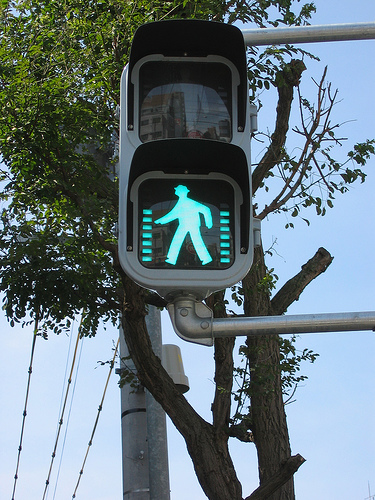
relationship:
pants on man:
[164, 224, 215, 267] [154, 184, 214, 265]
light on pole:
[113, 21, 255, 287] [171, 295, 374, 343]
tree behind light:
[0, 1, 375, 499] [113, 21, 255, 287]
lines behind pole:
[7, 297, 127, 498] [171, 295, 374, 343]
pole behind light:
[116, 288, 171, 498] [113, 21, 255, 287]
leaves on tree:
[0, 1, 372, 426] [0, 1, 375, 499]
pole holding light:
[241, 20, 373, 52] [113, 21, 255, 287]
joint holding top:
[168, 295, 214, 347] [113, 21, 255, 287]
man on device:
[165, 183, 201, 269] [113, 21, 255, 287]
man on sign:
[165, 183, 201, 269] [140, 182, 233, 268]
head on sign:
[171, 182, 193, 198] [140, 182, 233, 268]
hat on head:
[172, 182, 195, 192] [171, 182, 193, 198]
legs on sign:
[164, 224, 215, 267] [140, 182, 233, 268]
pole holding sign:
[171, 295, 374, 343] [140, 182, 233, 268]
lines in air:
[7, 297, 127, 498] [0, 1, 374, 499]